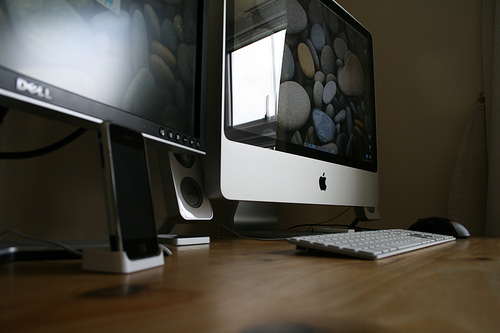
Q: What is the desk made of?
A: Wood.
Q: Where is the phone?
A: On the stand.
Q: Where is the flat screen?
A: On the right.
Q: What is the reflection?
A: The window.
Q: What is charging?
A: A phone.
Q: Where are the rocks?
A: On the monitor.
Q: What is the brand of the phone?
A: Apple.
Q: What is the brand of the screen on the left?
A: Dell.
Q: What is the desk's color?
A: Brown.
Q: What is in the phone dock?
A: The cell phone.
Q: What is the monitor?
A: The dell computer monitor.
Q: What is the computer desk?
A: The desk is wooden.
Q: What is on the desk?
A: The pair of computers.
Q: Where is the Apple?
A: The one on the right.